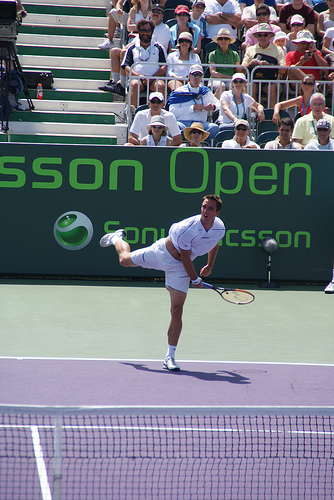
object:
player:
[98, 194, 226, 374]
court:
[4, 357, 330, 498]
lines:
[0, 414, 333, 446]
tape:
[1, 421, 333, 441]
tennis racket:
[192, 279, 256, 306]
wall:
[281, 156, 330, 281]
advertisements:
[104, 218, 314, 253]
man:
[285, 30, 326, 82]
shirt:
[284, 49, 329, 78]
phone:
[305, 45, 313, 59]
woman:
[166, 6, 201, 52]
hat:
[172, 2, 189, 19]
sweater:
[168, 23, 202, 46]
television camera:
[1, 2, 33, 135]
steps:
[5, 3, 125, 145]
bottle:
[33, 82, 45, 99]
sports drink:
[37, 91, 44, 101]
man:
[122, 20, 165, 110]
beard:
[136, 34, 154, 43]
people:
[141, 115, 174, 151]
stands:
[1, 4, 330, 150]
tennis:
[94, 195, 299, 393]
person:
[205, 29, 244, 78]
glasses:
[214, 37, 231, 43]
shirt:
[208, 48, 239, 75]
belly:
[163, 237, 184, 264]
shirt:
[171, 216, 226, 261]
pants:
[130, 238, 194, 293]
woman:
[178, 122, 211, 148]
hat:
[180, 122, 211, 137]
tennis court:
[3, 281, 333, 498]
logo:
[50, 211, 94, 254]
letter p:
[214, 146, 247, 211]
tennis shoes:
[99, 230, 132, 255]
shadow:
[123, 361, 251, 388]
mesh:
[4, 414, 332, 499]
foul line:
[1, 353, 332, 368]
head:
[199, 191, 225, 227]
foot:
[160, 357, 181, 374]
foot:
[100, 229, 125, 249]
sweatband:
[189, 278, 201, 286]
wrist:
[191, 276, 203, 286]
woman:
[218, 72, 264, 128]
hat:
[230, 71, 248, 84]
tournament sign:
[160, 148, 214, 197]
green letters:
[0, 150, 28, 195]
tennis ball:
[261, 238, 281, 253]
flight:
[260, 236, 279, 255]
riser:
[16, 44, 114, 58]